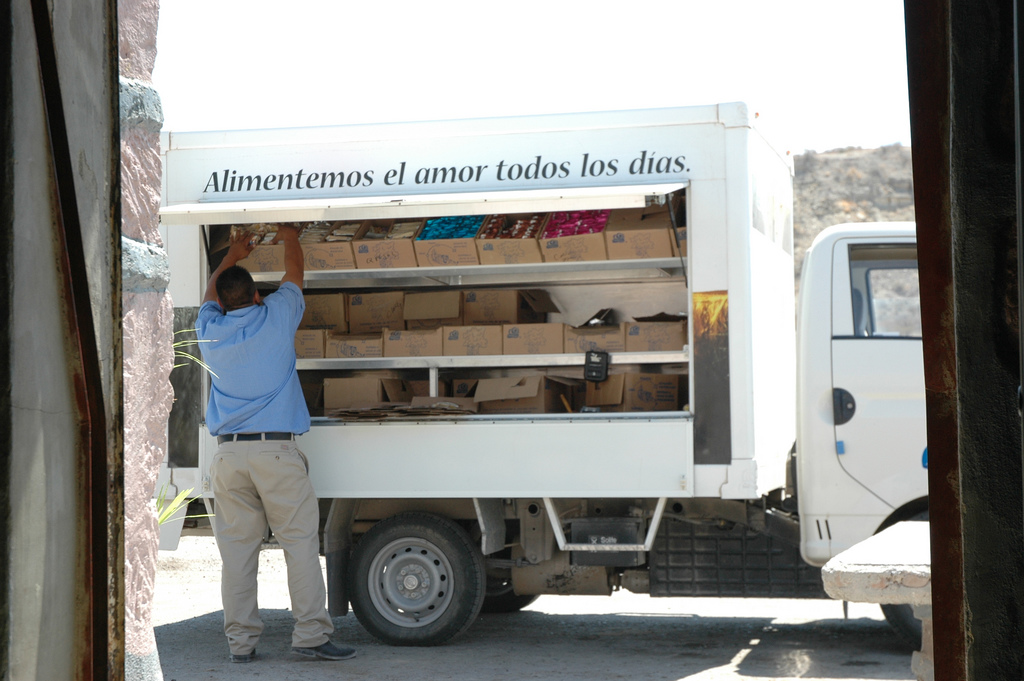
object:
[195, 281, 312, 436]
shirt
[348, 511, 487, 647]
tire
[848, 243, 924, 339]
window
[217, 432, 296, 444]
belt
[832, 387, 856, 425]
handle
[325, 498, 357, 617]
mudflap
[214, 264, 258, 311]
hair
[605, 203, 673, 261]
box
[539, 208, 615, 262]
box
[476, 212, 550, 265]
box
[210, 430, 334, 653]
pants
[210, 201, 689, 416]
boxes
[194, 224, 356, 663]
body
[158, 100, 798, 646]
truck